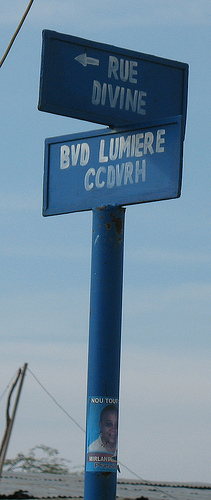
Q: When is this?
A: Daytime.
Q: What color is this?
A: Blue.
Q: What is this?
A: A post.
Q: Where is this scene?
A: On the street.